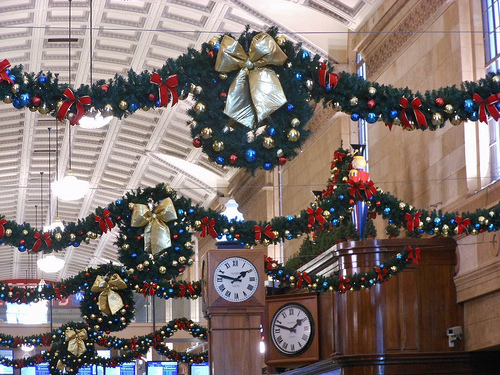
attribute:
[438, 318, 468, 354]
camera — on the right side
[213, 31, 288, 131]
bow — gold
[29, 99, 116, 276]
lights — white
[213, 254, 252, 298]
numbers — black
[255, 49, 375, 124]
balls — Red, Gold , Blue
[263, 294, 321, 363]
clock — white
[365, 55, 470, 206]
walls — beige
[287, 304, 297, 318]
roman numerals — black